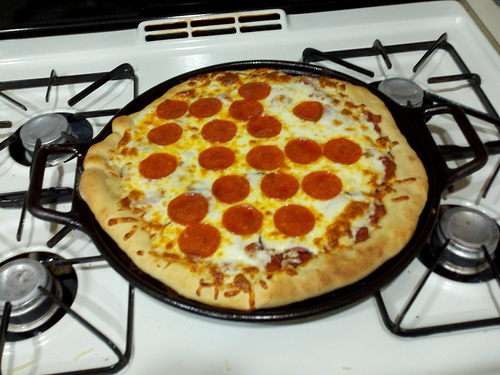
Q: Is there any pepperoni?
A: Yes, there is pepperoni.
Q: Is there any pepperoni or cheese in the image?
A: Yes, there is pepperoni.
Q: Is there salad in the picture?
A: No, there is no salad.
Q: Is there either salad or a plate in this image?
A: No, there are no salad or plates.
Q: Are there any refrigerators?
A: No, there are no refrigerators.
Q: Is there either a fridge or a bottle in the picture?
A: No, there are no refrigerators or bottles.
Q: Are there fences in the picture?
A: No, there are no fences.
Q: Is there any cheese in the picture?
A: Yes, there is cheese.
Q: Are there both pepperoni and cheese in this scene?
A: Yes, there are both cheese and pepperoni.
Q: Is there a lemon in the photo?
A: No, there are no lemons.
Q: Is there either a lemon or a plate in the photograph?
A: No, there are no lemons or plates.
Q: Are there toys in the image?
A: No, there are no toys.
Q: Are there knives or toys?
A: No, there are no toys or knives.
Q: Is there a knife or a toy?
A: No, there are no toys or knives.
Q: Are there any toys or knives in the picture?
A: No, there are no toys or knives.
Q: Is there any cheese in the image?
A: Yes, there is cheese.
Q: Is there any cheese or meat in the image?
A: Yes, there is cheese.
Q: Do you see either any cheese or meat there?
A: Yes, there is cheese.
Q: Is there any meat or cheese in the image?
A: Yes, there is cheese.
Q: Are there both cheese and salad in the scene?
A: No, there is cheese but no salad.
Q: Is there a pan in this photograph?
A: Yes, there is a pan.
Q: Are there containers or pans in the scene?
A: Yes, there is a pan.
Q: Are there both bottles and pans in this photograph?
A: No, there is a pan but no bottles.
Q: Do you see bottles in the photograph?
A: No, there are no bottles.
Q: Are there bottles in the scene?
A: No, there are no bottles.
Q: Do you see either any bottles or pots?
A: No, there are no bottles or pots.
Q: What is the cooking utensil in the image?
A: The cooking utensil is a pan.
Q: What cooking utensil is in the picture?
A: The cooking utensil is a pan.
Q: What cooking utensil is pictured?
A: The cooking utensil is a pan.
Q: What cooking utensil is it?
A: The cooking utensil is a pan.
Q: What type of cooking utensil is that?
A: This is a pan.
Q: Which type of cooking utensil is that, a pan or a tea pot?
A: This is a pan.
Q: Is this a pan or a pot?
A: This is a pan.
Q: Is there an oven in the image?
A: Yes, there is an oven.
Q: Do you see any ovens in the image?
A: Yes, there is an oven.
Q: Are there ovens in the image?
A: Yes, there is an oven.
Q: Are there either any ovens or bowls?
A: Yes, there is an oven.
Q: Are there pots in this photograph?
A: No, there are no pots.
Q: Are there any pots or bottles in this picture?
A: No, there are no pots or bottles.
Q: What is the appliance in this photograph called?
A: The appliance is an oven.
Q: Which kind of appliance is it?
A: The appliance is an oven.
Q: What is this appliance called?
A: That is an oven.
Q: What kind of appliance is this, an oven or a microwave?
A: That is an oven.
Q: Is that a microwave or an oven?
A: That is an oven.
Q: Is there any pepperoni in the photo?
A: Yes, there is pepperoni.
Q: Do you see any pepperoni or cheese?
A: Yes, there is pepperoni.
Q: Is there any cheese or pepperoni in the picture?
A: Yes, there is pepperoni.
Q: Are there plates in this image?
A: No, there are no plates.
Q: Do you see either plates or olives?
A: No, there are no plates or olives.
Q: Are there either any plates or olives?
A: No, there are no plates or olives.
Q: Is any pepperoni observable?
A: Yes, there is pepperoni.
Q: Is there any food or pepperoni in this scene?
A: Yes, there is pepperoni.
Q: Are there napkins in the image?
A: No, there are no napkins.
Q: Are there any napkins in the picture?
A: No, there are no napkins.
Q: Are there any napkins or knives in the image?
A: No, there are no napkins or knives.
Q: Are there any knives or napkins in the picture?
A: No, there are no napkins or knives.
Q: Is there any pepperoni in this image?
A: Yes, there is pepperoni.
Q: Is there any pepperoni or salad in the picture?
A: Yes, there is pepperoni.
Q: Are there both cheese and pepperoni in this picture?
A: Yes, there are both pepperoni and cheese.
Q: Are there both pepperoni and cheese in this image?
A: Yes, there are both pepperoni and cheese.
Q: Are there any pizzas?
A: Yes, there is a pizza.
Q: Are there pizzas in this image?
A: Yes, there is a pizza.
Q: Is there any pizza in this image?
A: Yes, there is a pizza.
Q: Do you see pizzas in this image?
A: Yes, there is a pizza.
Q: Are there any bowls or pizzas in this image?
A: Yes, there is a pizza.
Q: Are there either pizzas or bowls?
A: Yes, there is a pizza.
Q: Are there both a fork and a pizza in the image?
A: No, there is a pizza but no forks.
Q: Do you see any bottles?
A: No, there are no bottles.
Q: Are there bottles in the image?
A: No, there are no bottles.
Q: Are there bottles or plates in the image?
A: No, there are no bottles or plates.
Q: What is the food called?
A: The food is a pizza.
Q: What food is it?
A: The food is a pizza.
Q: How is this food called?
A: This is a pizza.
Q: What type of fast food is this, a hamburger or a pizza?
A: This is a pizza.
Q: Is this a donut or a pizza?
A: This is a pizza.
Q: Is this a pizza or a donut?
A: This is a pizza.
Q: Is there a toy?
A: No, there are no toys.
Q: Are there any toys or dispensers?
A: No, there are no toys or dispensers.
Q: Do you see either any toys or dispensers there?
A: No, there are no toys or dispensers.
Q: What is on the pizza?
A: The toppings are on the pizza.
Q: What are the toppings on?
A: The toppings are on the pizza.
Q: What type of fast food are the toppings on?
A: The toppings are on the pizza.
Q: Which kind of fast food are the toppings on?
A: The toppings are on the pizza.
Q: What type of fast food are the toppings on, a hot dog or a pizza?
A: The toppings are on a pizza.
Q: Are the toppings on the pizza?
A: Yes, the toppings are on the pizza.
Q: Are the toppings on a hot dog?
A: No, the toppings are on the pizza.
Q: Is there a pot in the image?
A: No, there are no pots.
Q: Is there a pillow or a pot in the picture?
A: No, there are no pots or pillows.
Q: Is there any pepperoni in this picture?
A: Yes, there is pepperoni.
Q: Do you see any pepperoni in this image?
A: Yes, there is pepperoni.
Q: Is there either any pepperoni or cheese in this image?
A: Yes, there is pepperoni.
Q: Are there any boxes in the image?
A: No, there are no boxes.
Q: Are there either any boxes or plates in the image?
A: No, there are no boxes or plates.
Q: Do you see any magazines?
A: No, there are no magazines.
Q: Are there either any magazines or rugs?
A: No, there are no magazines or rugs.